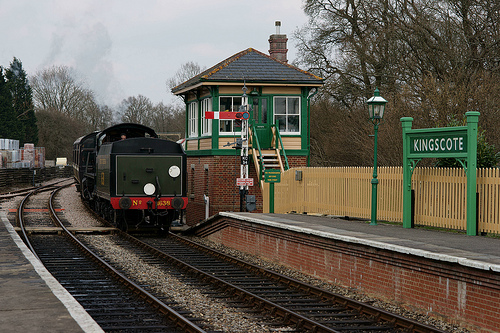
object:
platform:
[186, 212, 500, 273]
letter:
[457, 136, 467, 152]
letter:
[449, 136, 460, 152]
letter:
[443, 136, 455, 151]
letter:
[437, 137, 445, 151]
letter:
[426, 138, 436, 150]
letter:
[434, 138, 439, 149]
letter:
[411, 139, 419, 152]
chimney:
[267, 22, 287, 63]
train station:
[171, 20, 500, 273]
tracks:
[116, 231, 450, 332]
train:
[72, 121, 190, 235]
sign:
[406, 127, 471, 158]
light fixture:
[362, 88, 388, 224]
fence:
[263, 165, 500, 236]